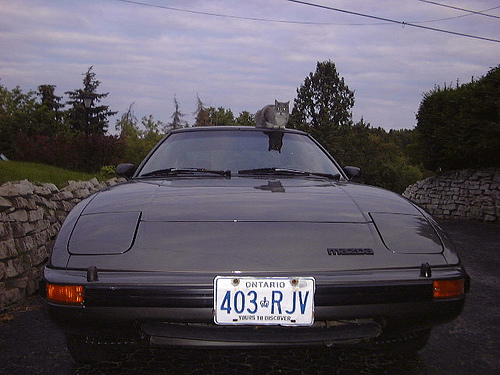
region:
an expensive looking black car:
[43, 126, 468, 368]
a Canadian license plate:
[213, 273, 316, 328]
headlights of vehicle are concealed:
[66, 208, 443, 267]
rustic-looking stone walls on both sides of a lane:
[0, 168, 496, 374]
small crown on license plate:
[257, 295, 270, 310]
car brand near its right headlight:
[320, 208, 440, 265]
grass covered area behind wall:
[0, 159, 105, 305]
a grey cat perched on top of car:
[237, 100, 294, 136]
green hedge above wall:
[413, 63, 496, 217]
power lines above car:
[58, 2, 496, 347]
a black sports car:
[8, 92, 497, 334]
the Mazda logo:
[315, 237, 387, 263]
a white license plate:
[195, 269, 336, 336]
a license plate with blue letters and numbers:
[202, 270, 329, 333]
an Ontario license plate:
[190, 265, 367, 337]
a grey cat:
[236, 79, 322, 135]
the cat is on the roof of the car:
[138, 77, 330, 156]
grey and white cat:
[237, 90, 315, 132]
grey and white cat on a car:
[232, 70, 299, 137]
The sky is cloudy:
[161, 23, 287, 72]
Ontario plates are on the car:
[178, 262, 365, 360]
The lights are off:
[31, 272, 96, 313]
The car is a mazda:
[305, 220, 400, 286]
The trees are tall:
[16, 10, 138, 172]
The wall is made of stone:
[5, 212, 66, 319]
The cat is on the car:
[245, 96, 302, 144]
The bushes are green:
[386, 75, 463, 167]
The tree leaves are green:
[258, 54, 373, 176]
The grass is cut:
[3, 156, 76, 200]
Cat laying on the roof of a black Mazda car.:
[41, 97, 469, 373]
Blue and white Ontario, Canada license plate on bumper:
[211, 275, 317, 327]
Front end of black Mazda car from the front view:
[40, 122, 468, 362]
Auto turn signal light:
[41, 278, 86, 305]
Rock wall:
[0, 175, 129, 322]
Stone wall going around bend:
[399, 172, 499, 224]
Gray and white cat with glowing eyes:
[251, 100, 292, 130]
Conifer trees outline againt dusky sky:
[3, 50, 414, 131]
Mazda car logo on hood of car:
[324, 244, 376, 260]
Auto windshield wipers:
[140, 165, 345, 182]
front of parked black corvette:
[39, 115, 472, 365]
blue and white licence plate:
[204, 271, 317, 331]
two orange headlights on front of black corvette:
[43, 273, 468, 311]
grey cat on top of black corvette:
[245, 92, 297, 130]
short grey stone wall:
[401, 152, 498, 224]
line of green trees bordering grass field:
[3, 60, 113, 168]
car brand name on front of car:
[317, 241, 378, 263]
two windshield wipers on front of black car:
[143, 160, 342, 189]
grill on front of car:
[141, 311, 389, 359]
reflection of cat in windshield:
[257, 128, 297, 150]